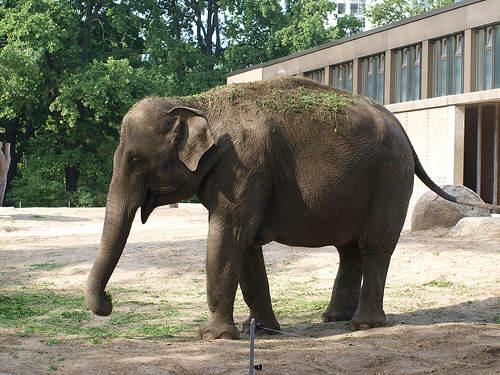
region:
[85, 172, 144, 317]
the trunk of an elephant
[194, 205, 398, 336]
the legs of an elephant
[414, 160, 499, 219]
the tail of an elephant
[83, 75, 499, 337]
a large brown elephant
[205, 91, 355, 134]
grass on the back of an elephant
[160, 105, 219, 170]
the ear of an elephant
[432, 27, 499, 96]
exterior windows on a building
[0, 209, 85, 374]
grass and dirt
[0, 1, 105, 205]
green trees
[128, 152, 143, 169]
the eye of an elephant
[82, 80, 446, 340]
Elephant in the center of photo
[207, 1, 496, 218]
Building behind the elephant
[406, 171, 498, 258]
Large rocks behind elephant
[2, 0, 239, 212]
Trees left of elephant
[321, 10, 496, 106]
Windows of building to the right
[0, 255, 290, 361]
Hay for elephant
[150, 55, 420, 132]
Hay on elephants back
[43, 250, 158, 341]
Elephant's trunk picking up hay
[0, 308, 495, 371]
Stake and wire around encloser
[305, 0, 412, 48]
Hi rise in right top corner of photo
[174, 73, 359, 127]
cut grass on an elephant's back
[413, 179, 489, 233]
a rounded mound of hay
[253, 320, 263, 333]
a black insulator on an electric fence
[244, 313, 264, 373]
a metal fence post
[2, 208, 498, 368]
the grass and dirt ground of an elephant enclosure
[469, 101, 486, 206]
a metal bar on a building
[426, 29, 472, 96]
windows in a building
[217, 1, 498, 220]
a brown building at a giraffe enclosure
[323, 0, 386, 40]
a white building visible above a brown building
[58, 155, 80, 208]
the brown trunk of a tree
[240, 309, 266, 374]
a post for a wire fence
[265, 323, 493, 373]
the wire of an electric fence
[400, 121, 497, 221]
a swinging elephant tail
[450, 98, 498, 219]
an opening into a building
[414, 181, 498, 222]
a mound of hay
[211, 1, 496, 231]
a brown building behind an elephant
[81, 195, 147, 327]
an elephant's trunk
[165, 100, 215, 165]
an elephant ear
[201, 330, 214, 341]
an elephant toenail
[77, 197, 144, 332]
trunk of an elephant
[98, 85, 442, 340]
a large grey elephant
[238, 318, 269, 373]
stake in the ground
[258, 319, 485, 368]
thin wire coming off of the stake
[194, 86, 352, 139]
green grass on top of elephant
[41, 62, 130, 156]
large coniferous trees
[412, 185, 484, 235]
medium sized grey boulder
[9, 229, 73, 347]
dirt with shredded grass on top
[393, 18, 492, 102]
window panes on a building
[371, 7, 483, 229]
cream and brown colored building